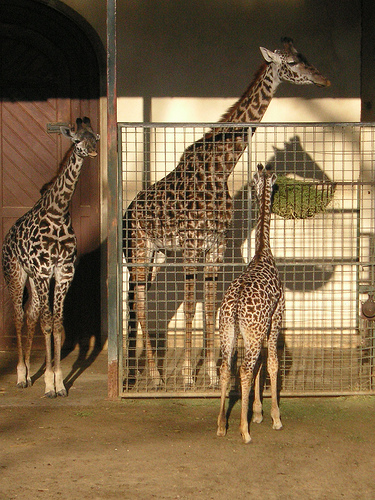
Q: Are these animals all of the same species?
A: Yes, all the animals are giraffes.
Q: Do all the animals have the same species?
A: Yes, all the animals are giraffes.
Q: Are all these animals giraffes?
A: Yes, all the animals are giraffes.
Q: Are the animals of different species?
A: No, all the animals are giraffes.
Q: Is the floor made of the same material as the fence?
A: No, the floor is made of concrete and the fence is made of metal.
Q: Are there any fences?
A: Yes, there is a fence.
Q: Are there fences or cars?
A: Yes, there is a fence.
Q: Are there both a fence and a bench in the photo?
A: No, there is a fence but no benches.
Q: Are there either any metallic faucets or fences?
A: Yes, there is a metal fence.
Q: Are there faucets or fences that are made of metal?
A: Yes, the fence is made of metal.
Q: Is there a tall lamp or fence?
A: Yes, there is a tall fence.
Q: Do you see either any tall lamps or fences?
A: Yes, there is a tall fence.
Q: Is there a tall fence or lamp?
A: Yes, there is a tall fence.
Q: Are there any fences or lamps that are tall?
A: Yes, the fence is tall.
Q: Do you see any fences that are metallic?
A: Yes, there is a metal fence.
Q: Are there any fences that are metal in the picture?
A: Yes, there is a metal fence.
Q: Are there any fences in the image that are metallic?
A: Yes, there is a fence that is metallic.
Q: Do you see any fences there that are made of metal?
A: Yes, there is a fence that is made of metal.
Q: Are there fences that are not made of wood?
A: Yes, there is a fence that is made of metal.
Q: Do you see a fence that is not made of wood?
A: Yes, there is a fence that is made of metal.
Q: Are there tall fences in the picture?
A: Yes, there is a tall fence.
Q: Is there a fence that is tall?
A: Yes, there is a fence that is tall.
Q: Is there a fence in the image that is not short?
A: Yes, there is a tall fence.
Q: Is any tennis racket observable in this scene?
A: No, there are no rackets.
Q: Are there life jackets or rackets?
A: No, there are no rackets or life jackets.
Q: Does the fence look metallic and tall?
A: Yes, the fence is metallic and tall.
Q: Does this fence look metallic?
A: Yes, the fence is metallic.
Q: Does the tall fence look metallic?
A: Yes, the fence is metallic.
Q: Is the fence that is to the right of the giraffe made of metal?
A: Yes, the fence is made of metal.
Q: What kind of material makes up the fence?
A: The fence is made of metal.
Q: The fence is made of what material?
A: The fence is made of metal.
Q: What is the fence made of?
A: The fence is made of metal.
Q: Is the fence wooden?
A: No, the fence is metallic.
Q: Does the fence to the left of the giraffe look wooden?
A: No, the fence is metallic.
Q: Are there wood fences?
A: No, there is a fence but it is made of metal.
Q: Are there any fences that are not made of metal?
A: No, there is a fence but it is made of metal.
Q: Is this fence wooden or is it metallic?
A: The fence is metallic.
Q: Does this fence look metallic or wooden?
A: The fence is metallic.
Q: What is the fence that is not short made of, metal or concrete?
A: The fence is made of metal.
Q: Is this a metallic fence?
A: Yes, this is a metallic fence.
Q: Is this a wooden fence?
A: No, this is a metallic fence.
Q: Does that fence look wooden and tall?
A: No, the fence is tall but metallic.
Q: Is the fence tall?
A: Yes, the fence is tall.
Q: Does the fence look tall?
A: Yes, the fence is tall.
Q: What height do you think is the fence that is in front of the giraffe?
A: The fence is tall.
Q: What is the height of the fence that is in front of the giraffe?
A: The fence is tall.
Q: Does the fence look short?
A: No, the fence is tall.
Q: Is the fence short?
A: No, the fence is tall.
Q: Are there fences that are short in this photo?
A: No, there is a fence but it is tall.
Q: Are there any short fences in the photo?
A: No, there is a fence but it is tall.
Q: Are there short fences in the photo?
A: No, there is a fence but it is tall.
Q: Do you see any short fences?
A: No, there is a fence but it is tall.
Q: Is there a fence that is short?
A: No, there is a fence but it is tall.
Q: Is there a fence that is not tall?
A: No, there is a fence but it is tall.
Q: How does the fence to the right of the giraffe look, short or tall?
A: The fence is tall.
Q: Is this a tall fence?
A: Yes, this is a tall fence.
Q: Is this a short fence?
A: No, this is a tall fence.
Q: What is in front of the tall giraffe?
A: The fence is in front of the giraffe.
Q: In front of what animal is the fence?
A: The fence is in front of the giraffe.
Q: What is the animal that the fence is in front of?
A: The animal is a giraffe.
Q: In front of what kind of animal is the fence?
A: The fence is in front of the giraffe.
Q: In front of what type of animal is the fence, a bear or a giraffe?
A: The fence is in front of a giraffe.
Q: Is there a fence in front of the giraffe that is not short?
A: Yes, there is a fence in front of the giraffe.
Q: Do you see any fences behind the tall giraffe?
A: No, the fence is in front of the giraffe.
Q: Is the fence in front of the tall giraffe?
A: Yes, the fence is in front of the giraffe.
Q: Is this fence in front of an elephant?
A: No, the fence is in front of the giraffe.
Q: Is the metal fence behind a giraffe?
A: No, the fence is in front of a giraffe.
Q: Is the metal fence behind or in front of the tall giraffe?
A: The fence is in front of the giraffe.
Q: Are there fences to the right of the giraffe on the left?
A: Yes, there is a fence to the right of the giraffe.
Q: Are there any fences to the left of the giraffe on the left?
A: No, the fence is to the right of the giraffe.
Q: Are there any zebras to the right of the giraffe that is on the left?
A: No, there is a fence to the right of the giraffe.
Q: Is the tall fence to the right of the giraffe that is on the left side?
A: Yes, the fence is to the right of the giraffe.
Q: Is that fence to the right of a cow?
A: No, the fence is to the right of the giraffe.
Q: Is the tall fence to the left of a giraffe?
A: No, the fence is to the right of a giraffe.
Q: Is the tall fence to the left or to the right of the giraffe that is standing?
A: The fence is to the right of the giraffe.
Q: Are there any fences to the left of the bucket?
A: Yes, there is a fence to the left of the bucket.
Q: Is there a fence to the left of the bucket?
A: Yes, there is a fence to the left of the bucket.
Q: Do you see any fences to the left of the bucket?
A: Yes, there is a fence to the left of the bucket.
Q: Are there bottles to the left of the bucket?
A: No, there is a fence to the left of the bucket.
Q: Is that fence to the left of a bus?
A: No, the fence is to the left of the bucket.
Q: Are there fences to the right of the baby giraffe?
A: No, the fence is to the left of the giraffe.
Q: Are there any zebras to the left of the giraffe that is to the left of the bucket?
A: No, there is a fence to the left of the giraffe.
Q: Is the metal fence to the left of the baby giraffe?
A: Yes, the fence is to the left of the giraffe.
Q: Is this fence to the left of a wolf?
A: No, the fence is to the left of the giraffe.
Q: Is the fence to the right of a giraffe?
A: No, the fence is to the left of a giraffe.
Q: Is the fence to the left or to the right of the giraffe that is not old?
A: The fence is to the left of the giraffe.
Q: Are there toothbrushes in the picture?
A: No, there are no toothbrushes.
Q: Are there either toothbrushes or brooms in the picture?
A: No, there are no toothbrushes or brooms.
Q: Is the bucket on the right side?
A: Yes, the bucket is on the right of the image.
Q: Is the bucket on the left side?
A: No, the bucket is on the right of the image.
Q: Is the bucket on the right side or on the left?
A: The bucket is on the right of the image.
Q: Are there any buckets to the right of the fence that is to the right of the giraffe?
A: Yes, there is a bucket to the right of the fence.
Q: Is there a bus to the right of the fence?
A: No, there is a bucket to the right of the fence.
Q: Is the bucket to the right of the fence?
A: Yes, the bucket is to the right of the fence.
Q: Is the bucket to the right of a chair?
A: No, the bucket is to the right of the fence.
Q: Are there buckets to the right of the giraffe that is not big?
A: Yes, there is a bucket to the right of the giraffe.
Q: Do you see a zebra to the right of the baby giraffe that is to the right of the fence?
A: No, there is a bucket to the right of the giraffe.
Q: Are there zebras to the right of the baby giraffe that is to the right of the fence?
A: No, there is a bucket to the right of the giraffe.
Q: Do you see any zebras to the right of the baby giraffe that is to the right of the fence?
A: No, there is a bucket to the right of the giraffe.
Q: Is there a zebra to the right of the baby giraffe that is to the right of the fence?
A: No, there is a bucket to the right of the giraffe.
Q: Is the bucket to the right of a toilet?
A: No, the bucket is to the right of the giraffe.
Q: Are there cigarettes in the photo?
A: No, there are no cigarettes.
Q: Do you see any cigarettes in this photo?
A: No, there are no cigarettes.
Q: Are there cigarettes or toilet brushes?
A: No, there are no cigarettes or toilet brushes.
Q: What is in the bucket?
A: The hay is in the bucket.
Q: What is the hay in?
A: The hay is in the bucket.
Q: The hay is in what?
A: The hay is in the bucket.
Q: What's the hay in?
A: The hay is in the bucket.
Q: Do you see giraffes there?
A: Yes, there is a giraffe.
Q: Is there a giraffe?
A: Yes, there is a giraffe.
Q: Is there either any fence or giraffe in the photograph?
A: Yes, there is a giraffe.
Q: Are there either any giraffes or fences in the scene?
A: Yes, there is a giraffe.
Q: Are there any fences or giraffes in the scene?
A: Yes, there is a giraffe.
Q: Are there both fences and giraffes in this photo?
A: Yes, there are both a giraffe and a fence.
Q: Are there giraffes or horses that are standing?
A: Yes, the giraffe is standing.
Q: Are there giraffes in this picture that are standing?
A: Yes, there is a giraffe that is standing.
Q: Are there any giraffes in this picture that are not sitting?
A: Yes, there is a giraffe that is standing.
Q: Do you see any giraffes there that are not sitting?
A: Yes, there is a giraffe that is standing .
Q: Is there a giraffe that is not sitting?
A: Yes, there is a giraffe that is standing.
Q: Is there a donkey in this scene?
A: No, there are no donkeys.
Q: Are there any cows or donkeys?
A: No, there are no donkeys or cows.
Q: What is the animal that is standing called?
A: The animal is a giraffe.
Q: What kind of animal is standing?
A: The animal is a giraffe.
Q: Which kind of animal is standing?
A: The animal is a giraffe.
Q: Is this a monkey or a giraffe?
A: This is a giraffe.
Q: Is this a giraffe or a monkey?
A: This is a giraffe.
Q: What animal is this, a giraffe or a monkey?
A: This is a giraffe.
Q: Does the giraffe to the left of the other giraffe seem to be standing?
A: Yes, the giraffe is standing.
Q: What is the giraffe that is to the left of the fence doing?
A: The giraffe is standing.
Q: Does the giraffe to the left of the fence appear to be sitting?
A: No, the giraffe is standing.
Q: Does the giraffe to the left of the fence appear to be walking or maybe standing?
A: The giraffe is standing.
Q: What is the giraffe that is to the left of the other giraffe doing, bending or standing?
A: The giraffe is standing.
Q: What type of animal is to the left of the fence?
A: The animal is a giraffe.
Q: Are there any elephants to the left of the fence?
A: No, there is a giraffe to the left of the fence.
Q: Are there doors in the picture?
A: Yes, there is a door.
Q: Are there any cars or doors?
A: Yes, there is a door.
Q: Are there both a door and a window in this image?
A: No, there is a door but no windows.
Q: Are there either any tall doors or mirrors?
A: Yes, there is a tall door.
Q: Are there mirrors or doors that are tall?
A: Yes, the door is tall.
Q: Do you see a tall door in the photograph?
A: Yes, there is a tall door.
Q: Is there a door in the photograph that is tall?
A: Yes, there is a door that is tall.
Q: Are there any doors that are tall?
A: Yes, there is a door that is tall.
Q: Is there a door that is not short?
A: Yes, there is a tall door.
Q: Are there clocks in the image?
A: No, there are no clocks.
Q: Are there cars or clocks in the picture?
A: No, there are no clocks or cars.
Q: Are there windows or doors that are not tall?
A: No, there is a door but it is tall.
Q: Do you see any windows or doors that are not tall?
A: No, there is a door but it is tall.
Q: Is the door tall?
A: Yes, the door is tall.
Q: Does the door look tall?
A: Yes, the door is tall.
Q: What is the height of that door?
A: The door is tall.